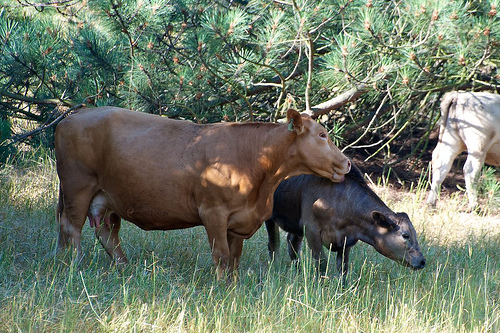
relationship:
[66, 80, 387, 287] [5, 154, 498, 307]
cow in field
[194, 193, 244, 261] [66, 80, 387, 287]
leg of cow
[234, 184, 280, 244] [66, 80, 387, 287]
haunch on cow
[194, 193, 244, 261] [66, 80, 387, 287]
leg on cow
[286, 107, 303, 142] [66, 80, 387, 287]
ear on cow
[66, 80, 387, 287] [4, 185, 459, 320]
cow in grass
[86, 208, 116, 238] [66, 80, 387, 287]
udders on cow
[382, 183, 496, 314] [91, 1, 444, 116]
shadows from tree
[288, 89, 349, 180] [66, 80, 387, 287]
head on cow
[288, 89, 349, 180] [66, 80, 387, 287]
head of cow